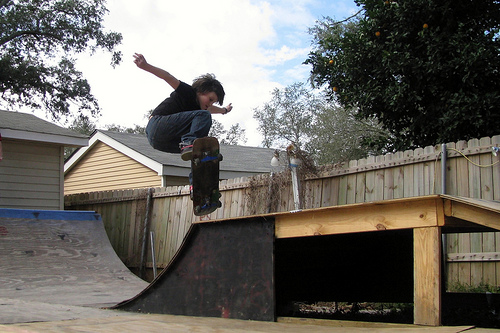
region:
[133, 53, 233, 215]
young man in black shirt on skateboard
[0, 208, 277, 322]
gray wooden skateboard ramp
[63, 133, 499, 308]
brown wooden fence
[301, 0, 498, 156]
orange tree with green leaves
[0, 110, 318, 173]
two roofs with gray shingles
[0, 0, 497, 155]
blue and white cloudy sky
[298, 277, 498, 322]
green weeds along fence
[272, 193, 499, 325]
wooden platform leading to skateboard ramp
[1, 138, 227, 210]
beige siding on two houses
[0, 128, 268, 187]
white painted trim on houses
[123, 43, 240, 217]
a boy jumping a ramp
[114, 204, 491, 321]
a wooden ramp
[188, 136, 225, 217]
the bottom of a skate board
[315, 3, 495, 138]
a tree with fruit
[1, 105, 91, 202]
a cream color building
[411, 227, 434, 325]
a wooden support leg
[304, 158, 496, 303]
a wooden fence behind a ramp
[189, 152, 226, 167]
wheels on a board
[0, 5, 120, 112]
a green leafy tree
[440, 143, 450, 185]
a gray metal pole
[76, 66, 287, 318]
a boy jumping a ramp on a skateboard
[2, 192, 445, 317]
a wood skateboard ramp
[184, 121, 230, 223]
a skateboard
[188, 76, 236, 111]
a boy with brown hair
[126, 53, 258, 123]
a boy with his arms stretched out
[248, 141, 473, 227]
a wood privacy fence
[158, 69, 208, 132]
a boy wearing a black shirt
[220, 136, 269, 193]
a building with a shingled roof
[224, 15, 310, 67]
white clouds in the sky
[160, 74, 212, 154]
a boy wearing jeans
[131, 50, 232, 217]
a boy doing a trick on a skateboard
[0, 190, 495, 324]
a wooden skateboard ramp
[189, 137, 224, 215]
a boy's wooden skateboard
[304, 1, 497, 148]
a large fruit tree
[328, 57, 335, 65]
an orange growing on a tree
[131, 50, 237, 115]
a boy's outstretched arms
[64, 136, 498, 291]
a large wooden fence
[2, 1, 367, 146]
a cloud covered sky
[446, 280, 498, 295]
weeds growing in front of a fence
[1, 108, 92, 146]
the roof of a house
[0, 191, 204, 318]
Homemade skate ramp in the yard.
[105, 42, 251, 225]
Boy riding his skateboard.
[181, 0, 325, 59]
Pale blue sky filled with clouds.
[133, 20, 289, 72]
White puffy clouds in the sky.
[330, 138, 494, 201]
Large wood fence for privacy.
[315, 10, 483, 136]
Large tree in the neighbors yard.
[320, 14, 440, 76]
Oranges on the tree.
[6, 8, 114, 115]
Green tree in the front yard.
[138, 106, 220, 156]
The boy is wearing grey pants.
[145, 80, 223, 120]
Boy wearing a black shirt.